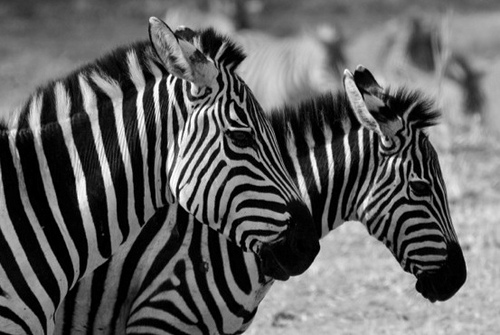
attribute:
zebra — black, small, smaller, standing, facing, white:
[1, 12, 328, 333]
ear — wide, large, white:
[146, 13, 220, 93]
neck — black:
[33, 91, 181, 262]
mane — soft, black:
[15, 25, 251, 125]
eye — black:
[226, 126, 254, 149]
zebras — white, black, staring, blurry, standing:
[3, 7, 473, 334]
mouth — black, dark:
[261, 240, 297, 278]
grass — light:
[242, 66, 499, 331]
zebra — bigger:
[21, 46, 321, 309]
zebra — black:
[325, 41, 466, 301]